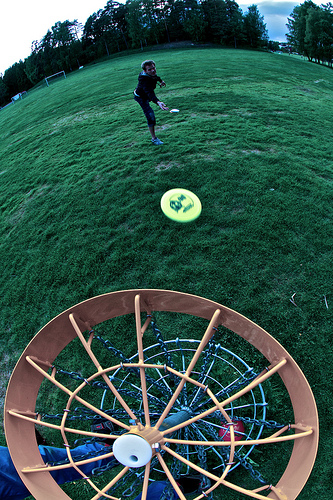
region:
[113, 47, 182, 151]
this is a person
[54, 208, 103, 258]
the grass is lush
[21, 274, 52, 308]
the grass is lush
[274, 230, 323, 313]
the grass is lush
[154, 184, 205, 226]
Frisbee flying over grass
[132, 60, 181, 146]
A man throwing a frisbee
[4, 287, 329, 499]
Overhead view of a frisbee golf goal.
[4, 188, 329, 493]
Frisbee heading for the goal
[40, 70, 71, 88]
soccer goal on a field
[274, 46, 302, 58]
parking lot for players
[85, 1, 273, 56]
trees for shade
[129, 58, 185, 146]
man hoping to score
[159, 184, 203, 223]
a yellow frisbee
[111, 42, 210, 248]
man threw the frisbee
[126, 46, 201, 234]
man threw the frisbee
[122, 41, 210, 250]
man threw the frisbee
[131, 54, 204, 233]
man threw the frisbee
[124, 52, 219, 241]
man threw the frisbee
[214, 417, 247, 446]
the ball is pink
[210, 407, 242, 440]
the ball is pink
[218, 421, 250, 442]
the ball is pink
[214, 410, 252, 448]
the ball is pink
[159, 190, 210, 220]
a frisbee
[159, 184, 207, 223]
a frisbee is light green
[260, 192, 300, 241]
the grass is short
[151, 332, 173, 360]
chains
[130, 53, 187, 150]
the man is throwing a frisbee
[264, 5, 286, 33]
a white cloud in the sky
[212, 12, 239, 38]
the bush is green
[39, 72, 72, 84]
a goal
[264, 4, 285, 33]
a cloud in the sky is white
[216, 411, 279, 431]
the chains are gray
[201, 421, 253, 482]
the chains are gray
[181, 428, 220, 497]
the chains are gray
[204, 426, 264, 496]
the chains are gray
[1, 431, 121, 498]
the pant is purple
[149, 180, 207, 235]
the frisbee is yellow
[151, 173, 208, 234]
the frisbee is yellow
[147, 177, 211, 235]
the frisbee is yellow